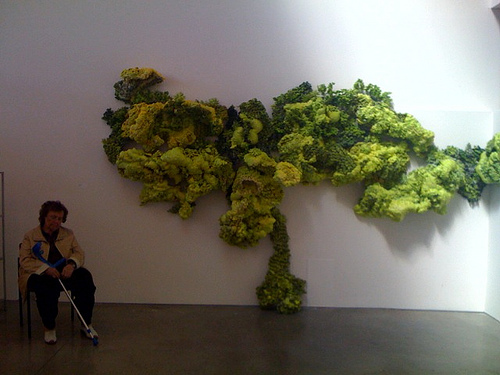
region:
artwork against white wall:
[98, 23, 493, 309]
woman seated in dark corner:
[1, 137, 103, 357]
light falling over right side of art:
[340, 10, 492, 315]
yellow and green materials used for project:
[95, 42, 495, 312]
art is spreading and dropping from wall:
[96, 41, 491, 311]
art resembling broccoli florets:
[95, 40, 490, 315]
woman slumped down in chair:
[10, 185, 105, 350]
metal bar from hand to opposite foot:
[15, 190, 120, 350]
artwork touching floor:
[235, 215, 320, 325]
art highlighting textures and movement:
[97, 41, 492, 306]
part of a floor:
[439, 334, 463, 342]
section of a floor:
[256, 351, 274, 358]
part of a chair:
[29, 309, 32, 320]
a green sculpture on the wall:
[251, 145, 288, 176]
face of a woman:
[53, 210, 64, 226]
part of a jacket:
[39, 245, 44, 250]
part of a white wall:
[409, 217, 457, 289]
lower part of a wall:
[478, 298, 488, 309]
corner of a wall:
[484, 242, 494, 298]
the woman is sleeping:
[27, 171, 149, 367]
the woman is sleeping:
[2, 178, 106, 318]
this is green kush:
[328, 78, 434, 220]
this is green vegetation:
[159, 117, 251, 215]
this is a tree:
[98, 71, 488, 352]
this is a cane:
[46, 259, 109, 354]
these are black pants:
[21, 257, 107, 339]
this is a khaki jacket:
[15, 221, 110, 301]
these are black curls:
[28, 191, 80, 226]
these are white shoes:
[21, 312, 114, 353]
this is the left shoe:
[71, 314, 112, 342]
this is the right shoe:
[25, 316, 64, 346]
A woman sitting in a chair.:
[11, 201, 99, 344]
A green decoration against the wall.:
[100, 66, 499, 311]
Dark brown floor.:
[2, 296, 499, 374]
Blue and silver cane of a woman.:
[32, 241, 98, 345]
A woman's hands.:
[43, 261, 78, 281]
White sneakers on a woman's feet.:
[39, 318, 101, 346]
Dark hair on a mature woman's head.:
[37, 201, 67, 225]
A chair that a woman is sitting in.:
[15, 241, 78, 340]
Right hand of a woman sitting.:
[45, 265, 62, 282]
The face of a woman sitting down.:
[44, 209, 64, 232]